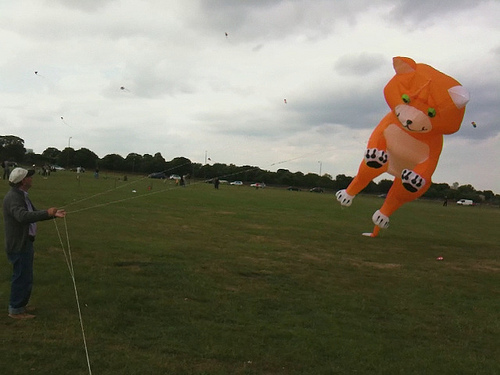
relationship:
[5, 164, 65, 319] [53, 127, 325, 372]
man holding string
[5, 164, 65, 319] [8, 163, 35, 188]
he has on hat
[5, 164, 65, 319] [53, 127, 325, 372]
he holding rope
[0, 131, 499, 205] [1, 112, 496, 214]
trees in background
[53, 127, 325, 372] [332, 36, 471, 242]
string attached to balloon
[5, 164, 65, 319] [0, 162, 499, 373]
man standing on grass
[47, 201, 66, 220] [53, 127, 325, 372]
hands holding string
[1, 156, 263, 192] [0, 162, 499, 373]
people on grass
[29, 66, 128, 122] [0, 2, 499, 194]
three kites in sky